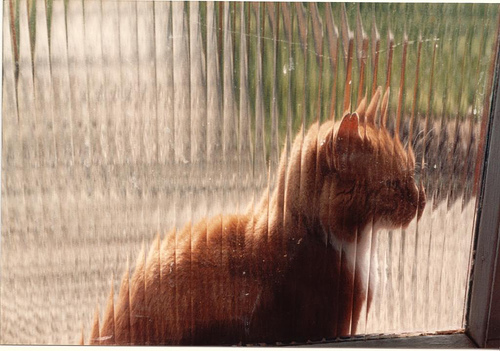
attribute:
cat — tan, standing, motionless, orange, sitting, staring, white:
[81, 84, 425, 338]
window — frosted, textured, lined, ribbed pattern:
[4, 3, 499, 346]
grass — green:
[188, 3, 480, 193]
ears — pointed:
[355, 87, 390, 127]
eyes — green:
[385, 179, 402, 190]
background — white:
[3, 0, 272, 243]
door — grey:
[466, 25, 499, 349]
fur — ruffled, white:
[319, 174, 373, 237]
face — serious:
[378, 171, 425, 227]